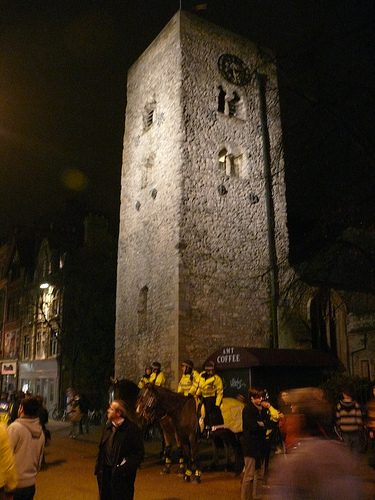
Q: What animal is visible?
A: Horse.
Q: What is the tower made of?
A: Stone.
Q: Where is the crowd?
A: On the street.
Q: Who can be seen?
A: A man in black.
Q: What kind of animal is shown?
A: Horse.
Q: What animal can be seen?
A: Horse.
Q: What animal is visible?
A: Horse.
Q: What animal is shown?
A: Horse.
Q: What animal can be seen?
A: Horse.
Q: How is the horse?
A: Visible.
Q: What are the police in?
A: Yellow jackets.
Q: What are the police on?
A: Horses.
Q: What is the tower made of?
A: Stone.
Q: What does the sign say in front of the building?
A: Amt coffee.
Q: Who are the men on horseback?
A: Police officers.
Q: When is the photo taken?
A: At night.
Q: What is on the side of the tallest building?
A: A clock.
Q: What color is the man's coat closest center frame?
A: Black.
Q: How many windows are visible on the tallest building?
A: Five.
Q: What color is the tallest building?
A: Grey.